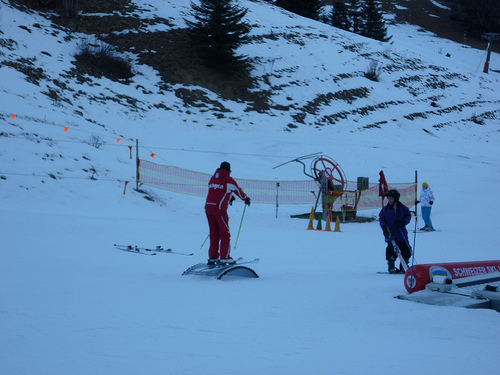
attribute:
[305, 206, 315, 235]
cone — four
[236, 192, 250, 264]
pole — ski, one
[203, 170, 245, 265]
suit — red, white, snow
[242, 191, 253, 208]
glove — black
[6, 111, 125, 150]
flag — red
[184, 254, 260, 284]
surface — semi circle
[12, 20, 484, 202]
hill — snow covered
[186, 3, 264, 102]
tree — evergreen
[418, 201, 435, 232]
pants — blue, snow, pair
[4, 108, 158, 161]
flag — orange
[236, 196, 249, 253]
pole — ski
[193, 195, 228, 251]
pole — ski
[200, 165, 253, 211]
jacket — white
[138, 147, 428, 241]
netting — orange safety 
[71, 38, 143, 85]
patches — grass 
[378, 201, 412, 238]
coat — blue 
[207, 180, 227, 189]
lettering — white 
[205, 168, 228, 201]
background — red 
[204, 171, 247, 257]
suit — red 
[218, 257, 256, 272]
skis — white 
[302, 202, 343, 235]
cones — green safety c, yellow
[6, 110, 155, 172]
flags — orange , row 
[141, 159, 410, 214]
barrier — mesh fence safety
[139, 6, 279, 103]
tree — pine 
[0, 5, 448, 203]
hillside — snowy 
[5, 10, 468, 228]
hillside — snowy 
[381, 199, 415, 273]
suit —  blue snow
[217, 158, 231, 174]
helmet — black sports safety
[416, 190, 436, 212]
coat — white 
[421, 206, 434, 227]
pants — blue 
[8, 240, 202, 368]
snow — white 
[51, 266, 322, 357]
snow — white 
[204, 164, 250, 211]
jacket — red 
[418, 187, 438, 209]
jacket — white 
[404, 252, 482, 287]
object —  barrel shaped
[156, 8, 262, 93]
tree — without snow.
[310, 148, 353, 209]
fan — large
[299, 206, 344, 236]
cones — orange